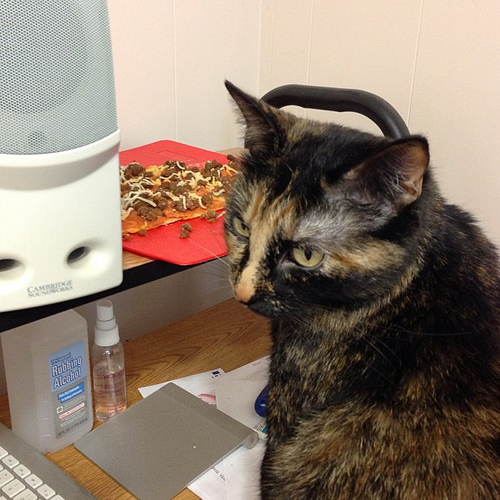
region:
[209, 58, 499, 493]
this is a cat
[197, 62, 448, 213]
set of cat ears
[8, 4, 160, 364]
white speaker on shelf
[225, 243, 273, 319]
nose of the cat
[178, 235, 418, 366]
whiskers on the cat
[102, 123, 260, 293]
pizza on a tray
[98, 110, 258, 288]
pizza tray is red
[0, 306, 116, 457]
a bottle of alcohol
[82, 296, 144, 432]
a clear spray bottle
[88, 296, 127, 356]
white nozzle on bottle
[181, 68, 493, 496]
a black and brown cat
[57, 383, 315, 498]
this is a wireless trackpad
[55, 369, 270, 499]
a computer track pad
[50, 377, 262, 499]
an Apple Computer track pad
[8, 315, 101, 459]
this is a bottle of rubbing alcohol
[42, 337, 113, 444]
this is the label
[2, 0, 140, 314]
a white and grey speaker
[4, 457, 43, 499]
the keys are white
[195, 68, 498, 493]
this is a cat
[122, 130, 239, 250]
this is a pizza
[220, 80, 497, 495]
a cat sitting on a table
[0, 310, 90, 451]
a plastic bottle next to a keyboard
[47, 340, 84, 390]
blue label on the plastic bottle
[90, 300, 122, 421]
a small spray bottle with a white top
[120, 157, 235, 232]
a slice of pizza on a red tray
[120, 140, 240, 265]
the red tray the pizza slice is on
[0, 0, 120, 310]
a large white speaker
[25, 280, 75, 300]
words on the white speaker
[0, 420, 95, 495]
edge of a keyboard next to bottle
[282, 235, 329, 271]
one of the cat's eyes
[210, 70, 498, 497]
a cat sitting in front of a computer.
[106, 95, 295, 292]
a plate of food on a desk.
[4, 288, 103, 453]
a bottle of alcohol on a desk.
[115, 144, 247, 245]
food on a red plate.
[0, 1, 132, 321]
a computer speaker on a desk.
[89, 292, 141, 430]
a spray bottle of alcohol.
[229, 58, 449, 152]
a bar on a desk.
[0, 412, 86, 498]
a computer keyboard on a desk.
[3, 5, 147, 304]
a speaker near a cat.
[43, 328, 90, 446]
a label on an alcohol bottle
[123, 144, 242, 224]
pizza on the red plate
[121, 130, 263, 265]
red plate on the desk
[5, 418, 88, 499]
gray keyboard with white keys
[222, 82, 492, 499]
black and blonde cat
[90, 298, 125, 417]
small spray bottle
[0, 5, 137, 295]
white speaker beside the pizza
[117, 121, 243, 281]
pizza on a red tray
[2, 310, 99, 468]
a bottle of alcohol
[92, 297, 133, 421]
a spray bottle by alcohol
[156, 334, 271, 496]
papers on the desk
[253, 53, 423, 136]
a black handle behind cat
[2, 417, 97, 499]
a grey keyboard on desk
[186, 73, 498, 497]
a cat sitting on desk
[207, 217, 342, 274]
the cat has green eyes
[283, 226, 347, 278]
eye is open wide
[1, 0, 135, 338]
a white speaker on desk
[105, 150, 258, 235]
slice of pizza on red mat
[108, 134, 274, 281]
red mat under pizza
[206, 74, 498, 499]
medium hair cat looking left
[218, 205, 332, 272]
yellow eyes of cat